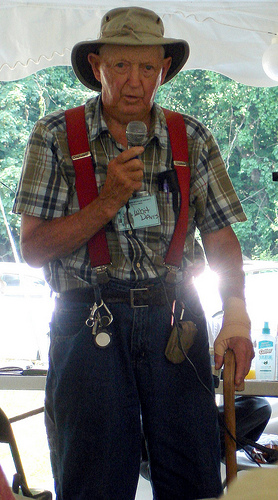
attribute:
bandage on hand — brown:
[207, 295, 261, 357]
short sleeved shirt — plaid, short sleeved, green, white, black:
[20, 104, 251, 285]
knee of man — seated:
[234, 386, 277, 427]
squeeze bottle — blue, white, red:
[253, 322, 276, 380]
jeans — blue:
[44, 280, 222, 498]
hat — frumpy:
[71, 6, 189, 92]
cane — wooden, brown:
[222, 345, 236, 493]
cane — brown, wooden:
[210, 345, 245, 493]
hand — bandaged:
[211, 315, 256, 387]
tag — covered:
[112, 189, 157, 236]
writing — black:
[132, 205, 160, 220]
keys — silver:
[85, 300, 113, 347]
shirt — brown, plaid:
[13, 94, 247, 288]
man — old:
[11, 5, 271, 484]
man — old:
[13, 7, 254, 498]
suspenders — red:
[162, 105, 188, 277]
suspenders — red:
[60, 100, 116, 272]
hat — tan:
[64, 3, 190, 91]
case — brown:
[162, 315, 200, 362]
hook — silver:
[165, 291, 185, 328]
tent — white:
[1, 0, 72, 74]